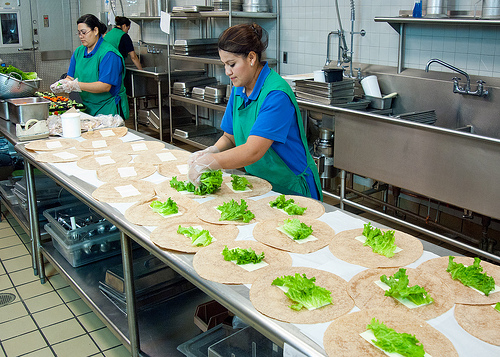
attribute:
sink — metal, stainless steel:
[285, 59, 499, 220]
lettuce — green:
[148, 172, 499, 354]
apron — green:
[232, 68, 322, 198]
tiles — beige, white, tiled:
[2, 202, 132, 356]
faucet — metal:
[424, 59, 490, 97]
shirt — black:
[104, 26, 133, 58]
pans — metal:
[134, 0, 367, 141]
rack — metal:
[172, 1, 283, 162]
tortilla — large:
[192, 237, 295, 285]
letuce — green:
[168, 170, 225, 198]